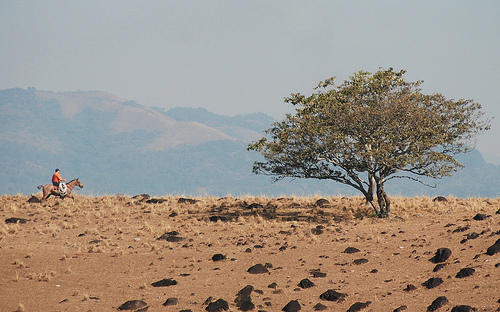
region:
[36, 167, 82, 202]
a horse and a horserider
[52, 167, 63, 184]
a horse rider wearing orange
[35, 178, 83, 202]
the big brown horse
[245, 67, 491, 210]
the only tree in the area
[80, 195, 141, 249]
the patches of brown grass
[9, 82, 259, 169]
the mountain tops in the distance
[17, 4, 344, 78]
the sky above the mountain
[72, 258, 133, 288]
the dirt on the ground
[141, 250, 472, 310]
the group of dark rocks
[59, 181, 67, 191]
the white rope on the horse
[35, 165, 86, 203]
man riding a horse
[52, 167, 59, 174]
hat on man's head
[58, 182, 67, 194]
rope hanging from horse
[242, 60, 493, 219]
tree growing in ground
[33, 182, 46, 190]
short tail on horse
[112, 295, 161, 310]
rock on the ground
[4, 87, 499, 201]
mountains on horizon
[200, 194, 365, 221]
shadow of tree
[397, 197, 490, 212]
patch of dead grass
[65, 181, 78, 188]
reins of horse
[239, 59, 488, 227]
large tree with green leaves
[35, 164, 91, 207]
person riding a horse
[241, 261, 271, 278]
rock in the dirt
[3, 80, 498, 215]
mountains in the distance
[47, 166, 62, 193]
person wearing orange shirt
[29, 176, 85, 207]
the horse is brown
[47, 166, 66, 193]
person wearing a hat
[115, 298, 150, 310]
rock in the dirt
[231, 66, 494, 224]
large tree in a field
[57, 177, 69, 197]
coil of white rope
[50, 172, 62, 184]
cowboy wearing a bright orange shirt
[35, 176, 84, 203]
brown horse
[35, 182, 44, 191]
a horses chopped off tail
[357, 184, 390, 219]
a few small trunks of trees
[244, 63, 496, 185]
dry bushy top of the tree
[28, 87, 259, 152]
dry hilly area of the mountain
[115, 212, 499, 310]
area of medium to small sized rocks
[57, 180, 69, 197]
lasso rope on the side of the cowboy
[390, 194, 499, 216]
thick dry area of grass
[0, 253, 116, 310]
dry sandy bare area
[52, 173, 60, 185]
an orange shirt on a rider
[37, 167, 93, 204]
a rider on a horse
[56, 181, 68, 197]
a white rope on a horse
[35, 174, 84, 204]
a brown horse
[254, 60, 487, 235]
a solitary tree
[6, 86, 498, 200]
a hill in the distance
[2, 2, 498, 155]
a grey sky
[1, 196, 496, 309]
a brown dirt hillside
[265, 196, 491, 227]
dry grass around a tree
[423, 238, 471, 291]
black rocks in th dirt